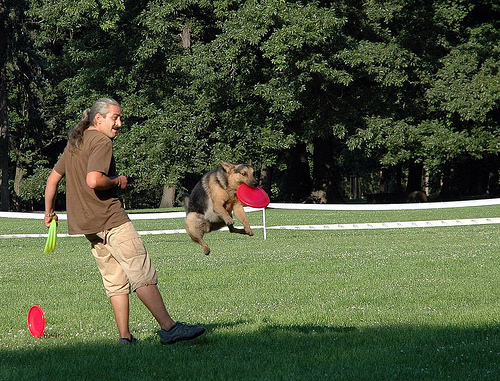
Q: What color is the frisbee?
A: Red.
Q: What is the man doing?
A: Watching the dog.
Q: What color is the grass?
A: Green.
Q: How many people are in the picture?
A: One.